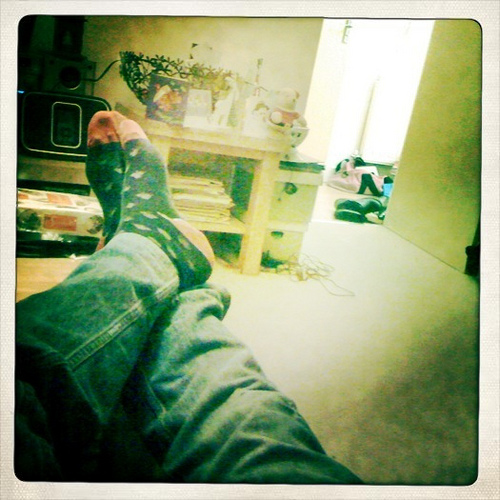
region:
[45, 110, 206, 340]
these are legs folded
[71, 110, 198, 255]
the feet are wearing socks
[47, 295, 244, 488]
the legs are wearing jeans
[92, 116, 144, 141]
the socks have orange strips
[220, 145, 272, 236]
this is a stand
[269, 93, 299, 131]
a teddy bear is on the wall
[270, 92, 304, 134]
the teddy bear is white in color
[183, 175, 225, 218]
the sheets are on the stand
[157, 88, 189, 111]
the book is on the stand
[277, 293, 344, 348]
the floor is bright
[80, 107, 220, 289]
black and pink ladies socks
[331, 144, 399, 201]
pink and black gym bag sitting on floor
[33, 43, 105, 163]
black stereo speaker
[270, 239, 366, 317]
tangled white electrical cords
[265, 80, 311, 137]
white stuffed teddy bear with pink shirt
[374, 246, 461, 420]
off white carpet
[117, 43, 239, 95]
decorative black basket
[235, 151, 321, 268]
white storage boxes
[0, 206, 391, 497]
person sitting with ankles crossed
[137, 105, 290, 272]
magazines stacked on white end table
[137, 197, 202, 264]
part of the left sock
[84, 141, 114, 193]
part of the right sock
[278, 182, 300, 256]
part of a white drawer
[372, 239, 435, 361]
part of a white floor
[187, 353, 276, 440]
part of a jeans trouser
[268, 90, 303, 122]
section of a doll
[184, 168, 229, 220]
pile of books under the table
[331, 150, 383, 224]
bunch of disarranged shoes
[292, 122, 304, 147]
part of a white bowl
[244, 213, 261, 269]
white stand of a table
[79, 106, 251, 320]
Person with socks on feet.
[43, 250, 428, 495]
Jeans on a sitting person.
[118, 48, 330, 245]
Items on a table.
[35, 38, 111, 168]
Electronic in the background.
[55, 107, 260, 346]
Black socks with polka dots.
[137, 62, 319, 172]
Picture frame on table.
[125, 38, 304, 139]
Black picture frame on the table.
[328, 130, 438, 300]
Items on the floor in background.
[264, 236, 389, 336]
Cord on carpeted floor.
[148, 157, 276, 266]
Magazines under a wooden table.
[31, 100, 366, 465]
legs extended in front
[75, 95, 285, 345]
legs crossed at ankle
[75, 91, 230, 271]
socks with red toes and heels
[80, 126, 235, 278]
pattern across dark background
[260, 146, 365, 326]
boxes and wires on floor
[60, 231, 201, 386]
inside seam of jeans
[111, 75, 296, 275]
open table filled with papers and objects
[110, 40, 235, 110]
open bowl of flowers and branches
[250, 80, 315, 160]
teddy bear sitting in container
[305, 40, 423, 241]
bright light coming from a different room